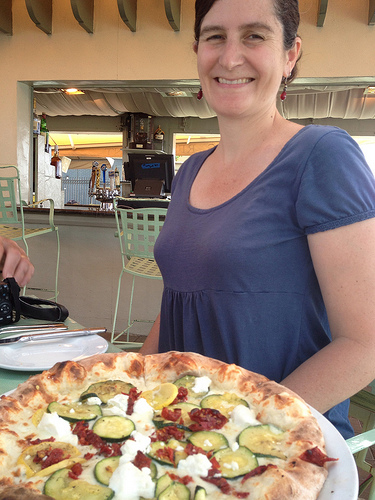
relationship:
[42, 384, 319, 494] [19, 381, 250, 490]
tomato sitting atop goat cheese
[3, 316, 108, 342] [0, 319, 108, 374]
knives resting on a plate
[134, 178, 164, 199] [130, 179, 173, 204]
back of computer monitor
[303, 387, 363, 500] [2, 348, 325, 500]
platter holding pizza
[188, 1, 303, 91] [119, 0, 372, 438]
hair of lady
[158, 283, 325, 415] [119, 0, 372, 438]
torso of lady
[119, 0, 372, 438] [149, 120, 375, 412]
lady with a shirt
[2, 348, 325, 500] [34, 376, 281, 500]
pizza with zucchini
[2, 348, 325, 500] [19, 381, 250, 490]
pizza with goat cheese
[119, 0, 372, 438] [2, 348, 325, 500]
lady beside a pizza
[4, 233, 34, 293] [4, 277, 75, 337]
hand holding strap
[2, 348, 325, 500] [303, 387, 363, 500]
pizza on a platter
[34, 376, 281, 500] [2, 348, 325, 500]
zucchini on pizza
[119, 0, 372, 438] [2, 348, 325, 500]
lady by pizza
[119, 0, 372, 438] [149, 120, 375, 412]
lady wearing a shirt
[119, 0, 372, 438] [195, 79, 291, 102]
lady has earrings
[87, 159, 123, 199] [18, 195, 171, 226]
beer taps are at bar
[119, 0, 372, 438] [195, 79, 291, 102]
lady wearing earrings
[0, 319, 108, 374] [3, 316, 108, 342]
plate with knives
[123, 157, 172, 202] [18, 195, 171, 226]
cash register at a bar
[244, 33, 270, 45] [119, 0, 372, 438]
eye of lady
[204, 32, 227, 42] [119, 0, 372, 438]
eye of lady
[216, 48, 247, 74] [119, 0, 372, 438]
nose of lady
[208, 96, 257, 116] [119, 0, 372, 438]
chin of lady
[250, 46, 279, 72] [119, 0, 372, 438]
cheek of lady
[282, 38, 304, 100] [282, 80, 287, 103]
ear with earring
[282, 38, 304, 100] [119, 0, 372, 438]
ear of lady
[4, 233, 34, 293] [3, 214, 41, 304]
hand of a person